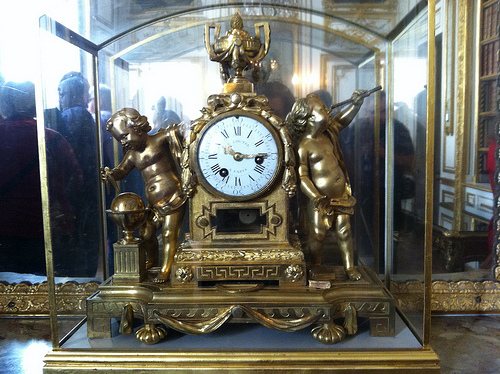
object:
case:
[30, 0, 444, 374]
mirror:
[94, 1, 392, 280]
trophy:
[202, 10, 273, 95]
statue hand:
[310, 194, 336, 217]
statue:
[104, 190, 153, 285]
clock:
[188, 107, 288, 203]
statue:
[83, 8, 398, 346]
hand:
[222, 145, 244, 162]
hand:
[233, 152, 268, 161]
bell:
[238, 210, 257, 225]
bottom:
[85, 264, 398, 346]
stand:
[39, 302, 445, 374]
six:
[234, 176, 242, 186]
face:
[107, 116, 143, 153]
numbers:
[233, 126, 242, 136]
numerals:
[220, 129, 230, 139]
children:
[98, 106, 198, 285]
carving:
[202, 10, 274, 83]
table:
[0, 312, 500, 374]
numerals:
[207, 153, 217, 160]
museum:
[0, 0, 500, 374]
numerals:
[210, 163, 222, 176]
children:
[283, 86, 373, 282]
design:
[169, 248, 308, 292]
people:
[0, 79, 86, 274]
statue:
[202, 10, 273, 84]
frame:
[421, 89, 437, 351]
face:
[311, 95, 334, 128]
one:
[246, 129, 254, 139]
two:
[254, 139, 266, 148]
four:
[253, 164, 266, 175]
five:
[247, 174, 262, 189]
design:
[194, 199, 285, 241]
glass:
[197, 114, 279, 196]